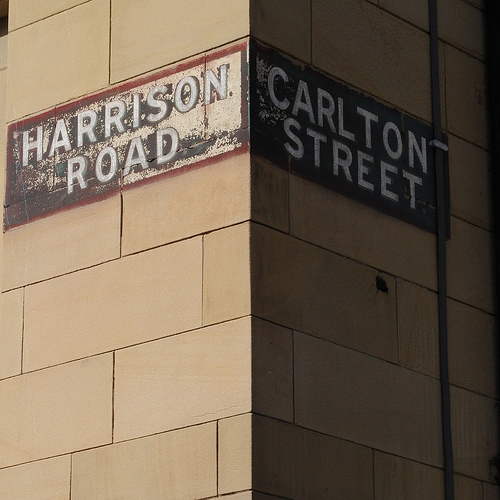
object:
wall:
[0, 0, 252, 499]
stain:
[373, 271, 389, 297]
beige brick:
[20, 233, 203, 377]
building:
[0, 0, 499, 498]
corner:
[226, 1, 264, 497]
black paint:
[176, 128, 214, 160]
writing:
[280, 112, 423, 218]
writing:
[20, 64, 231, 169]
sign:
[249, 33, 452, 241]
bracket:
[427, 140, 449, 157]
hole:
[369, 273, 391, 302]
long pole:
[426, 0, 455, 498]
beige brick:
[0, 191, 121, 295]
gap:
[289, 330, 296, 425]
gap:
[109, 350, 116, 444]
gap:
[198, 232, 205, 329]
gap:
[393, 277, 400, 363]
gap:
[19, 283, 26, 375]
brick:
[249, 218, 397, 366]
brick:
[291, 329, 445, 472]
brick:
[111, 314, 249, 443]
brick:
[0, 348, 113, 472]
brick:
[120, 152, 250, 259]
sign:
[5, 36, 251, 234]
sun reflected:
[0, 0, 250, 499]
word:
[65, 124, 182, 198]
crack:
[212, 421, 220, 498]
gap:
[118, 191, 124, 260]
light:
[0, 49, 250, 498]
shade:
[248, 1, 499, 499]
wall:
[247, 2, 497, 499]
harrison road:
[21, 63, 227, 195]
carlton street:
[265, 65, 427, 214]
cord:
[427, 0, 456, 498]